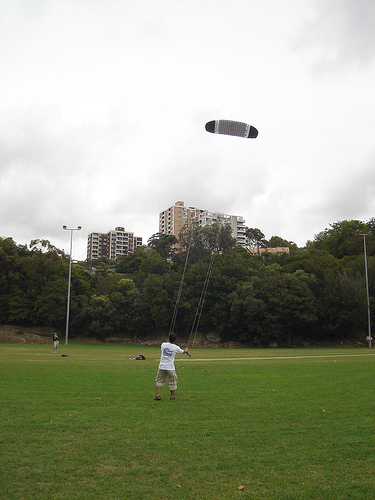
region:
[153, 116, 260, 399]
Man flying a kite in a park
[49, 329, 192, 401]
People in a park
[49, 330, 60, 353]
Woman wearing black and white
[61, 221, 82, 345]
Silver light pole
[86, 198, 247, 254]
Upper levels of condominium buildings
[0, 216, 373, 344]
Dense area of trees lining a park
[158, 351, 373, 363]
Empty sidewalk in a park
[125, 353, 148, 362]
Woman stretching on the ground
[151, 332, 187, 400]
Man wearing a white t-shirt and khakis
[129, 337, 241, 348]
Row of rocks under the trees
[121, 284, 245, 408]
A man at a park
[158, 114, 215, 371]
the man is holding a large kite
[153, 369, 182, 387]
the man is wearing shorts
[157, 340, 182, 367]
the man wears a white t shirt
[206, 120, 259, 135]
the kite is black grey and white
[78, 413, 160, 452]
the grass is cut short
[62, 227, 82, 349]
large light poles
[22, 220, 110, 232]
picture taken during the day time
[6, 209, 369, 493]
picture taken outside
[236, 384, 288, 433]
the grass is short and green.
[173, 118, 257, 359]
this guy is flying a kite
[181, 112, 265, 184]
this kite is black and grey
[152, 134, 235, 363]
this kite flyer is using four strings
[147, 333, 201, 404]
this man is wearing tan pants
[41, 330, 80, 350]
a person in the background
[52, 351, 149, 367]
items on the grass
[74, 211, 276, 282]
buildings above the trees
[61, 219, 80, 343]
a light pole in the scene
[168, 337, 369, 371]
some type of line on the ground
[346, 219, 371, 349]
a lamp pole near the trees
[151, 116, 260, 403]
man flying a kite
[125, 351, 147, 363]
person lying on ground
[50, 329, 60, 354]
person standing in distance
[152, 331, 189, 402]
man wearing tan shorts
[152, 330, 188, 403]
man with dark hair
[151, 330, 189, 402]
man wearing white shirt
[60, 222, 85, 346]
tall street light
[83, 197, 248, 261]
large apartment buildings behind trees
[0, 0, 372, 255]
gray, cloudy, dull sky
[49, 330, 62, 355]
person wearing white shoes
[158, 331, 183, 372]
Man wearing white shirt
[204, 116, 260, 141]
Black and white kite in the air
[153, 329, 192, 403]
Man flying a kite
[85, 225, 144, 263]
Building above the trees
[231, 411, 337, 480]
Green grassy field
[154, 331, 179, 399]
Man wearing tan colored shorts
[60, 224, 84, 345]
Light post in the field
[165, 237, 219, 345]
Strings attached to a kite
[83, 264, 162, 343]
Several dark green trees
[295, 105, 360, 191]
Dark cloud covered sky